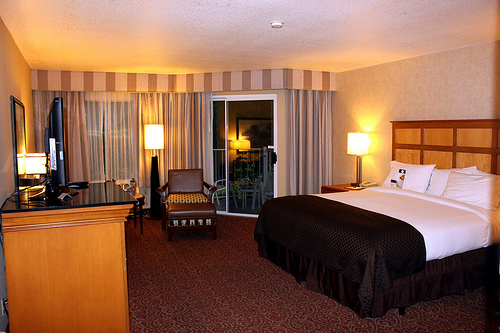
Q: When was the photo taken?
A: Night time.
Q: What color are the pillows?
A: White.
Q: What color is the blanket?
A: Black.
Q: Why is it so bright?
A: Lamps are on.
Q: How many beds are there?
A: One.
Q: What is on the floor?
A: Carpet.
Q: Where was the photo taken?
A: In a bedroom.